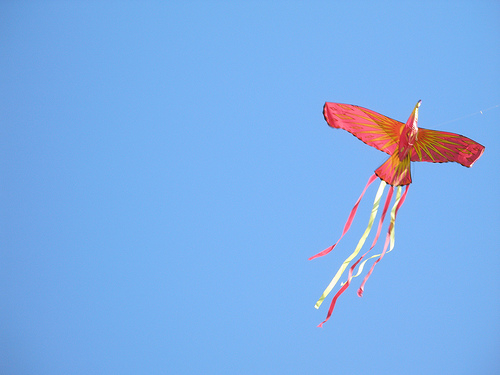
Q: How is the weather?
A: It is cloudless.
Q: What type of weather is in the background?
A: It is cloudless.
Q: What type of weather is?
A: It is cloudless.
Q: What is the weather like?
A: It is cloudless.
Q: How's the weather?
A: It is cloudless.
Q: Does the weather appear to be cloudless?
A: Yes, it is cloudless.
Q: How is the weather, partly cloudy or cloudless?
A: It is cloudless.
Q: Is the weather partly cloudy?
A: No, it is cloudless.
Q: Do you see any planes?
A: No, there are no planes.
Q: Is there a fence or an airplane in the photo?
A: No, there are no airplanes or fences.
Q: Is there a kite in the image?
A: Yes, there is a kite.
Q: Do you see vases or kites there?
A: Yes, there is a kite.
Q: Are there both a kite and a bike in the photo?
A: No, there is a kite but no bikes.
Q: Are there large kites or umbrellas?
A: Yes, there is a large kite.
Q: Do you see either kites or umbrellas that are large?
A: Yes, the kite is large.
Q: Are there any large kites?
A: Yes, there is a large kite.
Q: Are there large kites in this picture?
A: Yes, there is a large kite.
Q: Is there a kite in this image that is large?
A: Yes, there is a kite that is large.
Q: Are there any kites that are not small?
A: Yes, there is a large kite.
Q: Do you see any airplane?
A: No, there are no airplanes.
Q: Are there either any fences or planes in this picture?
A: No, there are no planes or fences.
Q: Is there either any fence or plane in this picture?
A: No, there are no airplanes or fences.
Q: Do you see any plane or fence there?
A: No, there are no airplanes or fences.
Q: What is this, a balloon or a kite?
A: This is a kite.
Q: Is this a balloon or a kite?
A: This is a kite.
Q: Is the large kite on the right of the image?
A: Yes, the kite is on the right of the image.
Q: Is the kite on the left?
A: No, the kite is on the right of the image.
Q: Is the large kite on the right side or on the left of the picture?
A: The kite is on the right of the image.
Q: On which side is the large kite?
A: The kite is on the right of the image.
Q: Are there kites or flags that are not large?
A: No, there is a kite but it is large.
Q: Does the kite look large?
A: Yes, the kite is large.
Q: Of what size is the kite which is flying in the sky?
A: The kite is large.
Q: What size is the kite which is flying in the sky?
A: The kite is large.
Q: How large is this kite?
A: The kite is large.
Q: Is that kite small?
A: No, the kite is large.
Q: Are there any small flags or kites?
A: No, there is a kite but it is large.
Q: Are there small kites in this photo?
A: No, there is a kite but it is large.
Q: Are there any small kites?
A: No, there is a kite but it is large.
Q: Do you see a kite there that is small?
A: No, there is a kite but it is large.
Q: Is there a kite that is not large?
A: No, there is a kite but it is large.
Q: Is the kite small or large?
A: The kite is large.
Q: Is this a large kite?
A: Yes, this is a large kite.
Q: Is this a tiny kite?
A: No, this is a large kite.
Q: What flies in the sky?
A: The kite flies in the sky.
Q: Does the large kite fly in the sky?
A: Yes, the kite flies in the sky.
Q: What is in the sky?
A: The kite is in the sky.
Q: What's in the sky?
A: The kite is in the sky.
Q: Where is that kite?
A: The kite is in the sky.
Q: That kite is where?
A: The kite is in the sky.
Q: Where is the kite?
A: The kite is in the sky.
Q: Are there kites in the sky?
A: Yes, there is a kite in the sky.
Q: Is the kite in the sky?
A: Yes, the kite is in the sky.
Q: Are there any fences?
A: No, there are no fences.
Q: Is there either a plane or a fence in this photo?
A: No, there are no fences or airplanes.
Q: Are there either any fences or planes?
A: No, there are no fences or planes.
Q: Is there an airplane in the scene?
A: No, there are no airplanes.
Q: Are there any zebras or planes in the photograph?
A: No, there are no planes or zebras.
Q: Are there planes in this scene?
A: No, there are no planes.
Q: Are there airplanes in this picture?
A: No, there are no airplanes.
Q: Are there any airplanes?
A: No, there are no airplanes.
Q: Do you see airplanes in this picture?
A: No, there are no airplanes.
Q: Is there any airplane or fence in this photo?
A: No, there are no airplanes or fences.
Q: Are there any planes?
A: No, there are no planes.